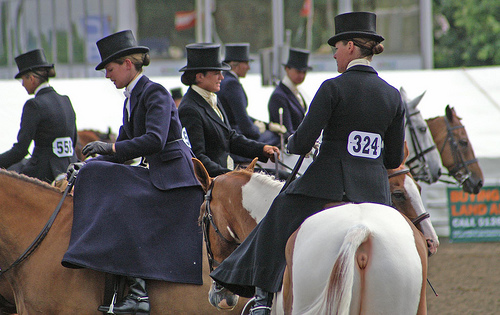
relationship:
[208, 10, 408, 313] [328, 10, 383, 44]
rider wearing hat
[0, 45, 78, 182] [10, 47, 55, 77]
rider wearing hat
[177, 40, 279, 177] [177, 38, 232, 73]
rider wearing hat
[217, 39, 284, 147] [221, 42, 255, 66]
rider wearing hat